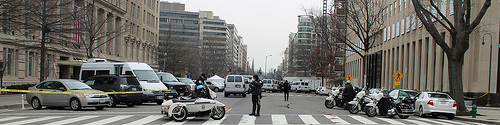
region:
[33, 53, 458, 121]
cars parked on a city street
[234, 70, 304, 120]
police officers standing in a city street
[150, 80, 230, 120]
police motorcycle in a city street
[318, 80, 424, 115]
police motorcycles parked on a city street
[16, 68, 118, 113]
silver car parked on a city street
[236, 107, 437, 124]
crosswalk painted on a city street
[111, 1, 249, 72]
tan brick building along a city street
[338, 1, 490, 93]
trees along the curb of a city street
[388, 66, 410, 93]
pedestrian crossing sign on a city street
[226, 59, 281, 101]
vans driving down a city street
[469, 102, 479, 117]
A green fire hydrant.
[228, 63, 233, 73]
A red traffic light.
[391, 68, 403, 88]
A black and yellow sign.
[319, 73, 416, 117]
Motorcycles.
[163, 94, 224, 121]
A sidecar on a motorcycle.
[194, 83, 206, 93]
A blue helmet.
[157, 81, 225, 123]
A person on a motorcycle.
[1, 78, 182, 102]
Yellow police tape.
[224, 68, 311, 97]
White vans.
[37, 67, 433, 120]
The road.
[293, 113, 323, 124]
thick white line on a street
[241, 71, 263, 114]
person dressed in all black in the middle of a street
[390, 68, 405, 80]
yellow pedestrian sign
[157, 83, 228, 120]
white motorcycle parked in the middle of a street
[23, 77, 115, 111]
gray vehicle parked on a street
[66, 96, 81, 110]
wheel of a vehicle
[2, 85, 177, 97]
yellow tape blocking off a section of the street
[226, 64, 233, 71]
red stop signal light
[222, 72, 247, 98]
white van on a street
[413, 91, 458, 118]
parked white vehicle on street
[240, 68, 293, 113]
two people standing in street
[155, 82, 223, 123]
motorcycle in middle of street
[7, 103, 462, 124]
white lines painted on the road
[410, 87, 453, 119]
white car parked on the street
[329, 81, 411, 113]
row of three motorcules parked on the street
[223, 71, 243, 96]
white van in the middle of the street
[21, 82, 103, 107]
gray car parked on the street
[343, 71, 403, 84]
yellow and black street sign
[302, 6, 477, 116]
trees along sidewalk on right side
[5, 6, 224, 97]
trees along sidewalk on the left side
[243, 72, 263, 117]
a standing police officer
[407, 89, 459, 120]
a white two door sedan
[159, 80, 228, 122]
a white motorcycle with sidecar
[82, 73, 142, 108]
a gray vehicle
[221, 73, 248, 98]
the back end of a white van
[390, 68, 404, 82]
a yellow crosswalk sign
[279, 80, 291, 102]
a person wearing black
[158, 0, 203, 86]
a tall building with glass windows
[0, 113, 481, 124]
a crosswalk with white painted lines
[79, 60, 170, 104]
a large white van